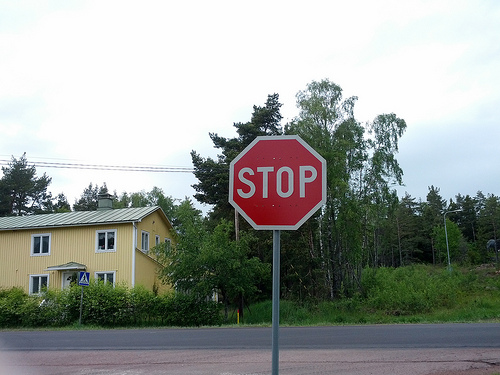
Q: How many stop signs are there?
A: One.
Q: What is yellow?
A: House.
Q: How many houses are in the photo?
A: One.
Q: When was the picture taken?
A: Daytime.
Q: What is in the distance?
A: Trees.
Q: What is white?
A: Sky.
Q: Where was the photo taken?
A: On the street.